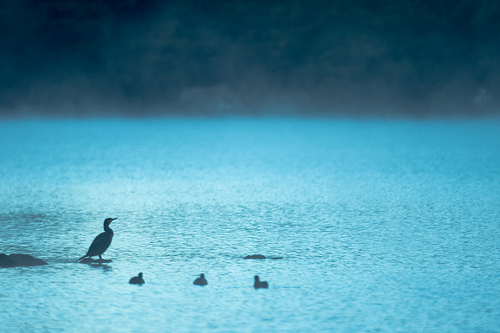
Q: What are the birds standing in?
A: Water.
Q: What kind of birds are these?
A: Ducks.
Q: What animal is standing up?
A: Duck.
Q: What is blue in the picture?
A: Water.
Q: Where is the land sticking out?
A: The left.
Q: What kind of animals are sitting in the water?
A: Ducks.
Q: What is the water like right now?
A: Calm.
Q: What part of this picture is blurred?
A: The background.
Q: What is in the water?
A: Birds.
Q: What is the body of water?
A: Bright blue.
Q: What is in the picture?
A: Four ducks.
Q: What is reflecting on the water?
A: The light.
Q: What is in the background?
A: The trees.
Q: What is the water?
A: Clear.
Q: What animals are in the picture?
A: Birds.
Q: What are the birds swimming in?
A: Water.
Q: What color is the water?
A: Blue.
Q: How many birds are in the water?
A: Three.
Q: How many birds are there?
A: Four.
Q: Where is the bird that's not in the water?
A: On a rock.